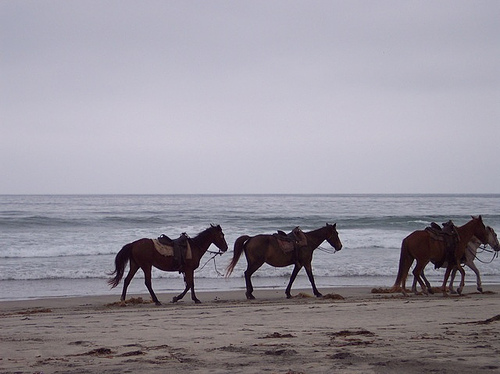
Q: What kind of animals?
A: Horses.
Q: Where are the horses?
A: On the beach.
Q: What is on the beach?
A: Horses.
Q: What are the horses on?
A: Sand.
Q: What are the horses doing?
A: Walking.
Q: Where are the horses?
A: On the beach.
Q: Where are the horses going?
A: For a walk.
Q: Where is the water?
A: Behind the horses.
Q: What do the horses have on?
A: Saddles.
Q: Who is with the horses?
A: Nobody is.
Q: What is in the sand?
A: Foot prints.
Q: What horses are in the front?
A: A brown and a white.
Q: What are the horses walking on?
A: The beach.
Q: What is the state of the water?
A: Calm.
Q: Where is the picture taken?
A: Shore.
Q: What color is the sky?
A: Grey.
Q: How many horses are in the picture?
A: Four.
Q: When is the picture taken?
A: Evening.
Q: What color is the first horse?
A: Tan.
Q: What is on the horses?
A: Saddles.